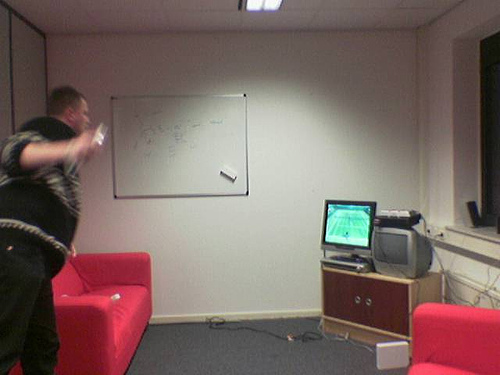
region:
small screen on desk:
[308, 201, 376, 251]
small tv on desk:
[368, 228, 432, 272]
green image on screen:
[325, 204, 370, 243]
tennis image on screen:
[320, 208, 369, 244]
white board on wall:
[119, 93, 258, 208]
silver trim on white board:
[237, 94, 260, 204]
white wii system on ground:
[371, 344, 421, 374]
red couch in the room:
[57, 248, 162, 374]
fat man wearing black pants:
[0, 83, 97, 370]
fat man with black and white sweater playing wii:
[5, 77, 97, 374]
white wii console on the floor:
[376, 335, 406, 373]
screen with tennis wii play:
[321, 201, 376, 253]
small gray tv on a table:
[370, 225, 437, 277]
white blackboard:
[108, 90, 249, 201]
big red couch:
[0, 247, 152, 374]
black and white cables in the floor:
[204, 317, 379, 362]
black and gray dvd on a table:
[322, 256, 371, 275]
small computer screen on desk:
[315, 201, 375, 248]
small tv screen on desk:
[310, 197, 376, 256]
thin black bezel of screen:
[317, 199, 373, 212]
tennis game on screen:
[327, 202, 369, 239]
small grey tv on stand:
[354, 225, 433, 277]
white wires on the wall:
[440, 258, 498, 303]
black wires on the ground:
[200, 305, 292, 359]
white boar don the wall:
[100, 82, 260, 208]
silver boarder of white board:
[241, 92, 249, 210]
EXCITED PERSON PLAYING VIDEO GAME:
[3, 77, 114, 372]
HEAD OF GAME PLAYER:
[42, 83, 90, 133]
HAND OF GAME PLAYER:
[76, 123, 113, 156]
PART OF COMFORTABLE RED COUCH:
[81, 260, 128, 281]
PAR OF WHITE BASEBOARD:
[161, 312, 189, 322]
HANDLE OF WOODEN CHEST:
[347, 291, 361, 305]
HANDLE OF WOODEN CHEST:
[362, 292, 377, 312]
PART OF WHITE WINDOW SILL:
[450, 226, 489, 256]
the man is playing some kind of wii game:
[1, 75, 139, 361]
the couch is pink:
[44, 238, 175, 370]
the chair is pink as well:
[393, 304, 494, 373]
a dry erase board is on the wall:
[108, 92, 272, 224]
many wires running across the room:
[433, 229, 496, 332]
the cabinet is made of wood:
[316, 251, 443, 343]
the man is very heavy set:
[0, 120, 101, 372]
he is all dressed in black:
[3, 113, 91, 370]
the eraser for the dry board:
[208, 155, 244, 204]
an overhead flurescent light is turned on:
[236, 0, 289, 17]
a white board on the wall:
[97, 68, 264, 203]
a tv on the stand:
[366, 213, 411, 270]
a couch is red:
[24, 249, 186, 368]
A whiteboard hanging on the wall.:
[108, 93, 252, 199]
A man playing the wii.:
[14, 83, 114, 369]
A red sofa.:
[40, 240, 150, 372]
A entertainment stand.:
[309, 248, 446, 362]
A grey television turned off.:
[370, 222, 433, 281]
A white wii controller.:
[69, 122, 109, 175]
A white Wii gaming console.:
[368, 339, 410, 372]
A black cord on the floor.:
[199, 315, 322, 350]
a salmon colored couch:
[45, 242, 160, 365]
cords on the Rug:
[202, 309, 324, 350]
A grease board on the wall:
[107, 86, 262, 211]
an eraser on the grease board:
[211, 158, 243, 188]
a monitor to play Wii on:
[315, 189, 377, 275]